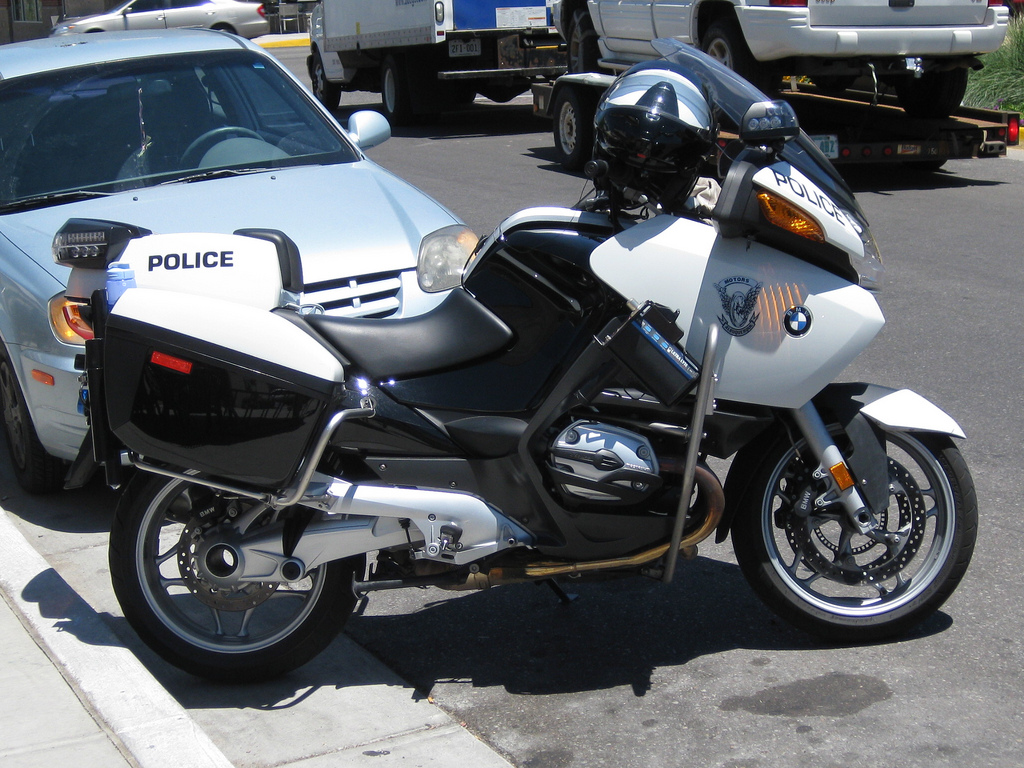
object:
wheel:
[380, 57, 421, 127]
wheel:
[307, 44, 345, 111]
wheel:
[555, 85, 596, 172]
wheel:
[725, 409, 980, 645]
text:
[148, 250, 233, 270]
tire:
[109, 469, 356, 685]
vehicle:
[309, 0, 604, 117]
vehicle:
[548, 0, 1008, 178]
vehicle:
[50, 38, 979, 684]